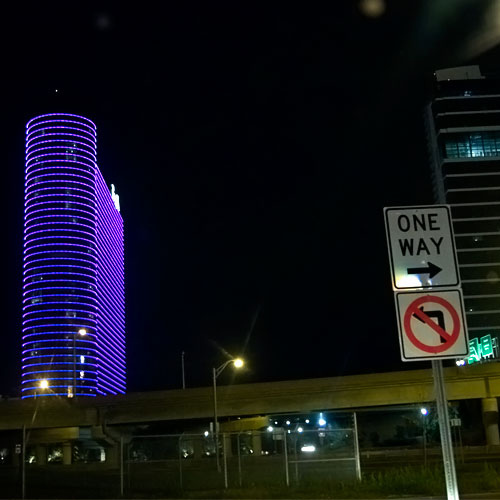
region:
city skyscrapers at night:
[27, 23, 491, 468]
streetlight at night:
[190, 321, 269, 494]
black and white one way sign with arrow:
[376, 185, 463, 293]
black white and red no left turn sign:
[376, 296, 493, 492]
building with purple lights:
[16, 103, 143, 390]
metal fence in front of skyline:
[120, 418, 357, 497]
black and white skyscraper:
[413, 57, 496, 355]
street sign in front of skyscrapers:
[372, 191, 477, 495]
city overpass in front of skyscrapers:
[13, 361, 479, 460]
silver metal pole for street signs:
[415, 347, 468, 497]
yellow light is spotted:
[224, 355, 236, 373]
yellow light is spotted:
[236, 360, 243, 362]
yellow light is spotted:
[237, 352, 244, 378]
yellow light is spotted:
[229, 356, 244, 377]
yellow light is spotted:
[233, 356, 241, 369]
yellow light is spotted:
[233, 360, 240, 363]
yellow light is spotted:
[232, 358, 237, 359]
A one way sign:
[384, 205, 462, 288]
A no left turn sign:
[393, 289, 469, 362]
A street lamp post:
[207, 355, 246, 432]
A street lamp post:
[70, 327, 91, 394]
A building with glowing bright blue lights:
[24, 114, 129, 398]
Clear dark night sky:
[124, 4, 389, 348]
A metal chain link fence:
[9, 433, 360, 488]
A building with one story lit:
[432, 70, 499, 331]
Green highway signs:
[460, 336, 496, 361]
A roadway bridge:
[3, 362, 498, 425]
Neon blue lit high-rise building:
[19, 112, 112, 400]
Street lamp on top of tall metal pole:
[207, 345, 252, 477]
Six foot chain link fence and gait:
[226, 413, 380, 484]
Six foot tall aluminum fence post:
[349, 409, 366, 481]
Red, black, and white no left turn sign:
[394, 286, 474, 364]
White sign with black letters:
[376, 201, 466, 291]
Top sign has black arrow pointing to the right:
[398, 259, 445, 282]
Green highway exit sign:
[476, 335, 491, 355]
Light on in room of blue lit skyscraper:
[36, 375, 46, 385]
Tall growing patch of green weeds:
[355, 471, 428, 486]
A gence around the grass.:
[58, 419, 370, 499]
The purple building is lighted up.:
[38, 101, 136, 393]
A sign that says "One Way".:
[361, 193, 476, 293]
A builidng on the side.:
[400, 68, 499, 258]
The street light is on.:
[201, 346, 260, 481]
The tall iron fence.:
[43, 422, 383, 483]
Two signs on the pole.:
[382, 207, 489, 480]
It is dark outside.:
[113, 51, 411, 352]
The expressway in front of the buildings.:
[30, 376, 486, 420]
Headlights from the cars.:
[278, 423, 345, 447]